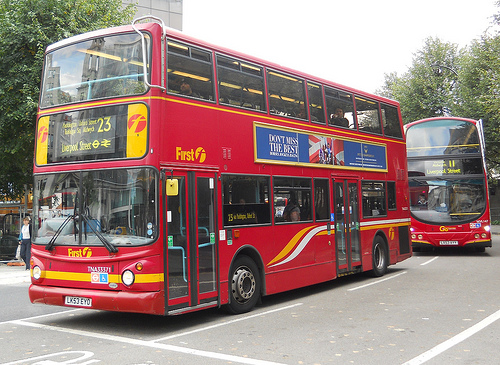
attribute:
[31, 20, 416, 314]
bus — red, double decker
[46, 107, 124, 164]
sign — black, yellow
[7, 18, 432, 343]
bus — red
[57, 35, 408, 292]
bus — double decker, large, red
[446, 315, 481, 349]
line — white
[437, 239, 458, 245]
licence plate — white, black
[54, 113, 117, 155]
sign — black, yellow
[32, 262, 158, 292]
yellow line — across